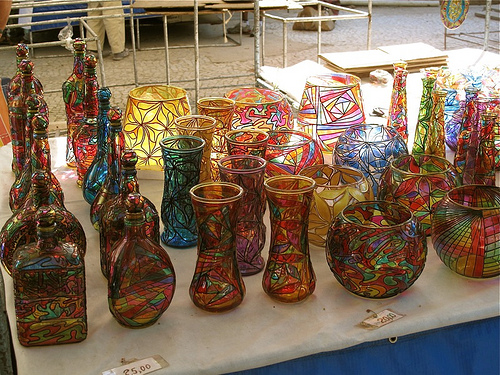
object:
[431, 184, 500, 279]
glassware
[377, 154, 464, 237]
glassware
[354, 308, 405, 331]
tag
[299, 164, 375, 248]
glassware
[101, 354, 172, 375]
tag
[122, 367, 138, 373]
25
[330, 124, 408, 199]
vase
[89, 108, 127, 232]
glassware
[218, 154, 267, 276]
glassware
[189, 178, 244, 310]
glassware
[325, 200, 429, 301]
vase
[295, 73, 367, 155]
glassware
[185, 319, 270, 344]
table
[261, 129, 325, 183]
vase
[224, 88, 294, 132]
vase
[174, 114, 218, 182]
vase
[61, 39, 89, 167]
vase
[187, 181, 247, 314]
glass vase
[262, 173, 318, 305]
glass vase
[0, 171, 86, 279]
glass vase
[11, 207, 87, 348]
glass vase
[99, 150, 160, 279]
glass vase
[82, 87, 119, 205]
glassware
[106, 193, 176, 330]
glass vase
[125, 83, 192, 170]
glass vase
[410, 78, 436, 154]
vase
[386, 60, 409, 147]
vase